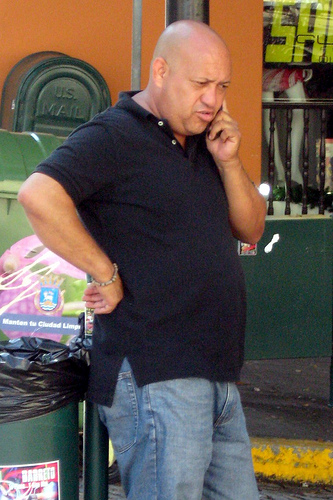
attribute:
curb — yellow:
[257, 437, 331, 486]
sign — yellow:
[263, 1, 331, 63]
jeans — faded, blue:
[95, 359, 273, 499]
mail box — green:
[0, 49, 112, 135]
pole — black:
[66, 371, 122, 494]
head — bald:
[148, 17, 230, 134]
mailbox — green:
[0, 49, 110, 136]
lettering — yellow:
[268, 6, 332, 70]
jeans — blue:
[98, 356, 261, 497]